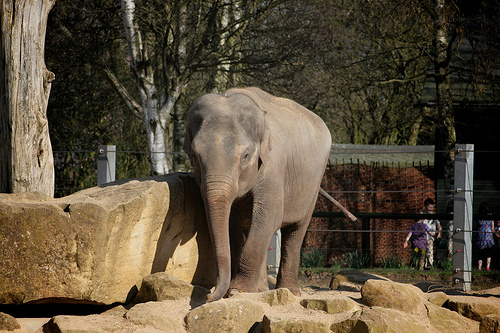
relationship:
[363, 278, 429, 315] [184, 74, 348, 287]
rock left elephant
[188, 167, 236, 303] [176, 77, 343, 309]
trunk of elephant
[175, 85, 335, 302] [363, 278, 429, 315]
elephant on rock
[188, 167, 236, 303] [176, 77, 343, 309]
trunk on an elephant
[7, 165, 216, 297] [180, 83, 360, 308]
rock beside an elephant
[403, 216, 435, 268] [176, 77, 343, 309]
child playing near an elephant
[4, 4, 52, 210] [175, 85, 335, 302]
tree trunk near an elephant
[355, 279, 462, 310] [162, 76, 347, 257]
rock near an elephant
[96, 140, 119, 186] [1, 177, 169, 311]
post near a rock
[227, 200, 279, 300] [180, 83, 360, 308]
front leg on an elephant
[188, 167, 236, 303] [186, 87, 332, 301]
trunk of an elephant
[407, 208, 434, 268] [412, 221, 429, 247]
child wearing purple shirt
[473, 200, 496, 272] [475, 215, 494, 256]
girl in a dress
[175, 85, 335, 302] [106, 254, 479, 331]
elephant standing on rocks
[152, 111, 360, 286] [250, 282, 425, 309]
elephant walking on rocks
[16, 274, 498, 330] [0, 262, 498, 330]
rocks along ground